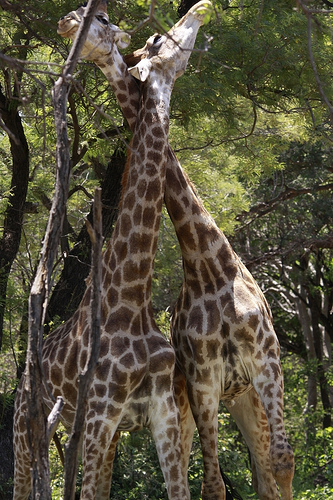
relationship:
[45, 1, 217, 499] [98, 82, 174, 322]
giraffe has a neck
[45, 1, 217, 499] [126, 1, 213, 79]
giraffe has a head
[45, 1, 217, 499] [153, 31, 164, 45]
giraffe has a eye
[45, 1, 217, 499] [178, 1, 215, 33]
giraffe has a mouth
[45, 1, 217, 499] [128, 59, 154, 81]
giraffe has a ear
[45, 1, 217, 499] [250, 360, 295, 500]
giraffe has a leg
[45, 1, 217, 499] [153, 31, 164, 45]
giraffe has an eye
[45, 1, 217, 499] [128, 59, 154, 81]
giraffe has an ear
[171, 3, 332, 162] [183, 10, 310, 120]
tree has leaves